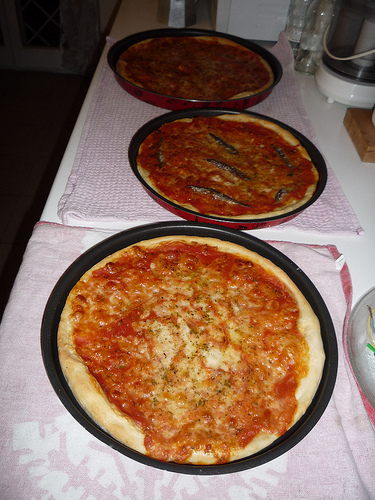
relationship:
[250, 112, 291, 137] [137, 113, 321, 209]
crust of pizza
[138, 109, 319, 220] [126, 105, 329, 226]
pizza on a pizza pan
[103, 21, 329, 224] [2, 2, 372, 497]
two pizzas on a table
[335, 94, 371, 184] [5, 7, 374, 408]
block on a table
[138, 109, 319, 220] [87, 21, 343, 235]
pizza on a pan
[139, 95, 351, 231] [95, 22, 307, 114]
pizza on a pan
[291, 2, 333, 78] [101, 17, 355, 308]
bottle on table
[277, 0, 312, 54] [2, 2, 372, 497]
glass on table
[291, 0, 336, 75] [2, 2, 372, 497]
glass on table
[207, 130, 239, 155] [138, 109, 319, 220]
anchovies on pizza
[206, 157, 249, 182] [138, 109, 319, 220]
anchovies on pizza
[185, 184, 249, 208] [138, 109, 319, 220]
anchovies on pizza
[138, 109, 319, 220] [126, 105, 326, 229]
pizza on pan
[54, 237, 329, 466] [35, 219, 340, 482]
cheese pizza on black dish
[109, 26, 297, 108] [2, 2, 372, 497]
pizzas on table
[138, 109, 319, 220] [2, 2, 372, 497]
pizza on table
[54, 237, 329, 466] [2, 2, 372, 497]
cheese pizza on table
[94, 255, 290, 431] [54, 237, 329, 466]
melted cheese on cheese pizza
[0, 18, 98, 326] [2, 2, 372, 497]
floor under table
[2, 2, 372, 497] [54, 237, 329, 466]
table beneath cheese pizza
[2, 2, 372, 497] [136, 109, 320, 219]
table beneath pizza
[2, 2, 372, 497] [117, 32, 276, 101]
table beneath pizza